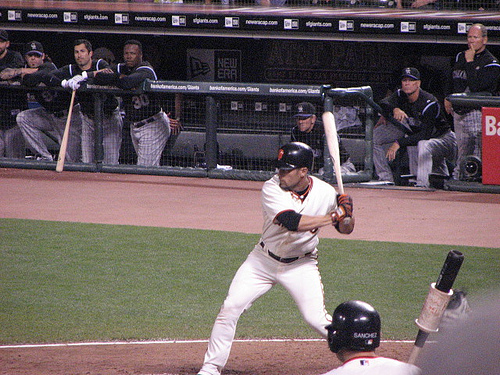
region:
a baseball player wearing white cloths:
[190, 94, 368, 372]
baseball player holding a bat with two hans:
[228, 94, 380, 274]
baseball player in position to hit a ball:
[193, 96, 370, 373]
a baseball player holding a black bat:
[291, 247, 468, 373]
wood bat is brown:
[317, 107, 366, 215]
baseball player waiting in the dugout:
[1, 30, 181, 175]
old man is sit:
[363, 60, 448, 186]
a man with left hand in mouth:
[450, 22, 499, 120]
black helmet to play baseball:
[316, 297, 397, 372]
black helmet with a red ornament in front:
[258, 132, 323, 179]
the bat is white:
[318, 112, 344, 186]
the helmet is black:
[282, 142, 310, 167]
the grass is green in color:
[122, 250, 165, 284]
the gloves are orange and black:
[328, 200, 363, 225]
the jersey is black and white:
[123, 78, 145, 110]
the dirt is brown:
[386, 203, 449, 225]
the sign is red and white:
[483, 104, 498, 151]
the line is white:
[51, 330, 138, 366]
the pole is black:
[204, 103, 229, 146]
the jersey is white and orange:
[267, 197, 303, 223]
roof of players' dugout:
[196, 4, 420, 24]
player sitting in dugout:
[286, 88, 337, 140]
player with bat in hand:
[198, 113, 360, 365]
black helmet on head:
[268, 138, 323, 184]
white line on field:
[120, 321, 187, 353]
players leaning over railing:
[32, 34, 154, 94]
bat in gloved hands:
[55, 74, 89, 130]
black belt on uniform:
[251, 243, 328, 270]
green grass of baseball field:
[67, 238, 174, 308]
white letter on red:
[479, 110, 498, 149]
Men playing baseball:
[2, 5, 493, 372]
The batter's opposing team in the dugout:
[4, 37, 201, 170]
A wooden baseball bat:
[315, 107, 360, 219]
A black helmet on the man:
[275, 139, 315, 176]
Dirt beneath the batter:
[242, 342, 307, 364]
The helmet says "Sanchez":
[350, 328, 380, 338]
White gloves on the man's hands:
[61, 66, 91, 96]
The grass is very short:
[42, 229, 179, 318]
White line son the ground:
[63, 334, 150, 351]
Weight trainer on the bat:
[411, 279, 449, 336]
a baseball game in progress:
[7, 7, 489, 362]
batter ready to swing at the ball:
[247, 103, 361, 360]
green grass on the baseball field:
[8, 225, 201, 325]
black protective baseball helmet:
[323, 293, 385, 355]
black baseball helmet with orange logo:
[270, 140, 317, 178]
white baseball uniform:
[252, 187, 332, 288]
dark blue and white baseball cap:
[397, 66, 419, 81]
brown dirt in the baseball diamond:
[23, 347, 189, 373]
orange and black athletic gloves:
[328, 185, 359, 238]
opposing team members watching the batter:
[11, 40, 169, 155]